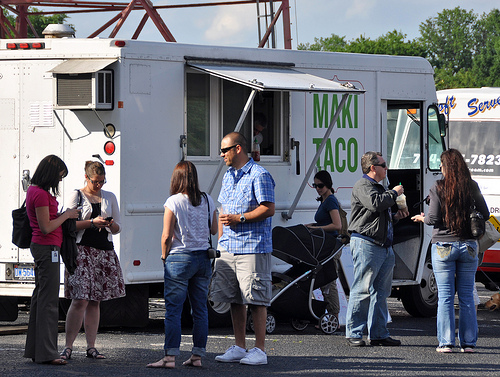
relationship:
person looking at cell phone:
[57, 157, 127, 364] [101, 214, 115, 224]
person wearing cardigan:
[57, 157, 127, 364] [66, 162, 123, 243]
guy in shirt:
[211, 131, 276, 364] [209, 158, 277, 252]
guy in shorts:
[211, 131, 276, 364] [209, 247, 276, 307]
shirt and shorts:
[209, 158, 277, 252] [209, 247, 276, 307]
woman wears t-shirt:
[312, 170, 345, 331] [312, 190, 348, 241]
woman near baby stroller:
[303, 170, 351, 342] [267, 228, 339, 333]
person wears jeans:
[407, 148, 492, 354] [432, 241, 479, 345]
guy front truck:
[211, 131, 276, 364] [0, 25, 446, 328]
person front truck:
[141, 158, 219, 368] [0, 25, 446, 328]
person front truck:
[57, 157, 130, 364] [0, 25, 446, 328]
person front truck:
[10, 151, 70, 366] [0, 25, 446, 328]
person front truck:
[407, 142, 492, 354] [0, 25, 446, 328]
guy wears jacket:
[343, 144, 410, 357] [342, 233, 397, 342]